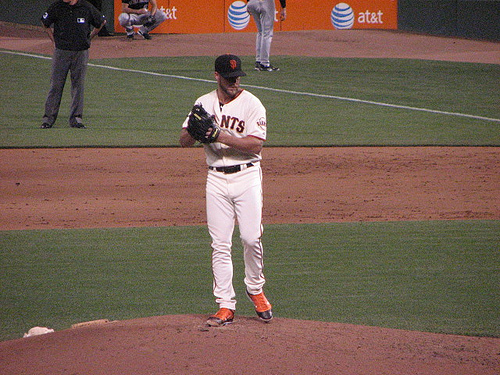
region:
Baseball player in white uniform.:
[173, 55, 280, 335]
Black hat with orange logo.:
[212, 53, 248, 79]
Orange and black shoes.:
[192, 291, 276, 326]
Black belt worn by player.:
[205, 156, 261, 173]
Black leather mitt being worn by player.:
[185, 99, 220, 146]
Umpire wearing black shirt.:
[36, 4, 108, 129]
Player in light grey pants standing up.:
[244, 2, 289, 74]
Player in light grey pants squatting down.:
[120, 1, 166, 38]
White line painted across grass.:
[4, 43, 499, 136]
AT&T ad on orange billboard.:
[113, 1, 399, 35]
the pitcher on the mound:
[167, 47, 297, 346]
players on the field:
[10, 5, 332, 91]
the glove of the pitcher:
[179, 92, 228, 156]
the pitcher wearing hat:
[207, 47, 250, 81]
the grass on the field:
[10, 232, 498, 337]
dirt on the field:
[10, 144, 497, 234]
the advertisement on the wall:
[158, 0, 392, 35]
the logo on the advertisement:
[326, 5, 391, 35]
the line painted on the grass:
[280, 82, 494, 149]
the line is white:
[303, 77, 497, 136]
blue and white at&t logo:
[330, 2, 355, 28]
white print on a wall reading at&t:
[355, 7, 385, 24]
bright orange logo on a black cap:
[227, 56, 238, 69]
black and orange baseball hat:
[212, 51, 249, 79]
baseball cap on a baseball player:
[213, 50, 250, 79]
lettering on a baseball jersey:
[216, 113, 247, 133]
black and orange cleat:
[249, 290, 276, 320]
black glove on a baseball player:
[183, 102, 223, 146]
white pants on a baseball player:
[203, 159, 269, 310]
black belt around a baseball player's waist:
[205, 160, 259, 174]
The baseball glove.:
[186, 101, 220, 143]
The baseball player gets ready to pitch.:
[180, 58, 275, 323]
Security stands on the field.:
[35, 5, 101, 131]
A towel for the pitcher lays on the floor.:
[22, 322, 54, 341]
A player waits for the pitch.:
[244, 3, 284, 71]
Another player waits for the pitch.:
[113, 3, 170, 38]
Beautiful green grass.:
[317, 229, 434, 309]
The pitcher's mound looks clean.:
[175, 325, 345, 368]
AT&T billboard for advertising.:
[319, 3, 401, 26]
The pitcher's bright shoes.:
[208, 309, 236, 327]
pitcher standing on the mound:
[169, 53, 314, 347]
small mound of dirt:
[0, 312, 499, 372]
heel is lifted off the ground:
[245, 285, 278, 322]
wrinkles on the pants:
[206, 234, 238, 270]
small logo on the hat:
[227, 58, 242, 73]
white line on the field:
[0, 41, 499, 130]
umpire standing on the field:
[36, 0, 106, 129]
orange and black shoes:
[198, 290, 278, 335]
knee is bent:
[234, 229, 266, 260]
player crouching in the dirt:
[117, 0, 177, 44]